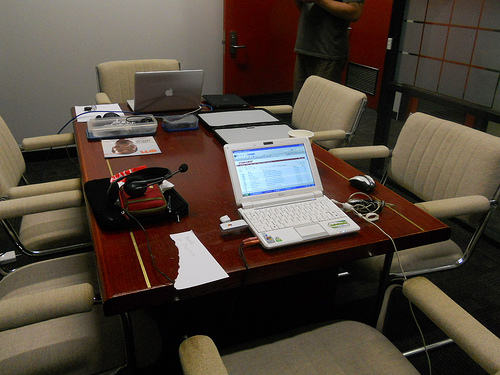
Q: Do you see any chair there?
A: Yes, there is a chair.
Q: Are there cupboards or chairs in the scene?
A: Yes, there is a chair.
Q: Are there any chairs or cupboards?
A: Yes, there is a chair.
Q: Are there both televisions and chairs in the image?
A: No, there is a chair but no televisions.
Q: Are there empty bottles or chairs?
A: Yes, there is an empty chair.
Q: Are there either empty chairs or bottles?
A: Yes, there is an empty chair.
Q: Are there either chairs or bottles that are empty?
A: Yes, the chair is empty.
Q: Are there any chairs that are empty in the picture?
A: Yes, there is an empty chair.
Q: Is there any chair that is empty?
A: Yes, there is a chair that is empty.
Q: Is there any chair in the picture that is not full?
A: Yes, there is a empty chair.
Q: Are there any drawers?
A: No, there are no drawers.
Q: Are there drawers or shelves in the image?
A: No, there are no drawers or shelves.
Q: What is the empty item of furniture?
A: The piece of furniture is a chair.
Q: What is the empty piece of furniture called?
A: The piece of furniture is a chair.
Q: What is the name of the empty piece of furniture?
A: The piece of furniture is a chair.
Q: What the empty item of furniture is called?
A: The piece of furniture is a chair.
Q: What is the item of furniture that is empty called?
A: The piece of furniture is a chair.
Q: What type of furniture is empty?
A: The furniture is a chair.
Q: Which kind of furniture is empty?
A: The furniture is a chair.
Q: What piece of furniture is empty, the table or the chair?
A: The chair is empty.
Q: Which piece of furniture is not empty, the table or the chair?
A: The table is not empty.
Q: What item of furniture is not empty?
A: The piece of furniture is a table.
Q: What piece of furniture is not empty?
A: The piece of furniture is a table.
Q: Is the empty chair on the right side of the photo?
A: Yes, the chair is on the right of the image.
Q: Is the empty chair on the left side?
A: No, the chair is on the right of the image.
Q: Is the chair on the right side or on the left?
A: The chair is on the right of the image.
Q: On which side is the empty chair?
A: The chair is on the right of the image.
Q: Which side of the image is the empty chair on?
A: The chair is on the right of the image.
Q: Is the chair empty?
A: Yes, the chair is empty.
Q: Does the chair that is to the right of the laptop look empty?
A: Yes, the chair is empty.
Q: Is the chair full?
A: No, the chair is empty.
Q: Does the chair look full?
A: No, the chair is empty.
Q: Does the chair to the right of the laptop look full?
A: No, the chair is empty.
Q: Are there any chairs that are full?
A: No, there is a chair but it is empty.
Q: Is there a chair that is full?
A: No, there is a chair but it is empty.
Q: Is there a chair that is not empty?
A: No, there is a chair but it is empty.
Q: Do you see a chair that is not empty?
A: No, there is a chair but it is empty.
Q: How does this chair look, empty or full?
A: The chair is empty.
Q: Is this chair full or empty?
A: The chair is empty.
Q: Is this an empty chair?
A: Yes, this is an empty chair.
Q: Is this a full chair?
A: No, this is an empty chair.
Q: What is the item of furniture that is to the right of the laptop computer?
A: The piece of furniture is a chair.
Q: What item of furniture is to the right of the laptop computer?
A: The piece of furniture is a chair.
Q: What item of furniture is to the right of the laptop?
A: The piece of furniture is a chair.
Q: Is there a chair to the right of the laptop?
A: Yes, there is a chair to the right of the laptop.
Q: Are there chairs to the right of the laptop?
A: Yes, there is a chair to the right of the laptop.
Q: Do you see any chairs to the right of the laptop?
A: Yes, there is a chair to the right of the laptop.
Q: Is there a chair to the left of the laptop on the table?
A: No, the chair is to the right of the laptop computer.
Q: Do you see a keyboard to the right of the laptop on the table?
A: No, there is a chair to the right of the laptop.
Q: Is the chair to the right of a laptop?
A: Yes, the chair is to the right of a laptop.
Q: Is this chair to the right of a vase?
A: No, the chair is to the right of a laptop.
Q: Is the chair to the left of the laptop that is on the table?
A: No, the chair is to the right of the laptop.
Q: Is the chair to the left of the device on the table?
A: No, the chair is to the right of the laptop.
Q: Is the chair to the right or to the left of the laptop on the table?
A: The chair is to the right of the laptop.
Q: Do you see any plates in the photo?
A: No, there are no plates.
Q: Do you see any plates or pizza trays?
A: No, there are no plates or pizza trays.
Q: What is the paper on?
A: The paper is on the table.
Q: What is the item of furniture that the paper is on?
A: The piece of furniture is a table.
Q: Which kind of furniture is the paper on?
A: The paper is on the table.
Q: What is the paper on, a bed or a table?
A: The paper is on a table.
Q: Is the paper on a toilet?
A: No, the paper is on the table.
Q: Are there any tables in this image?
A: Yes, there is a table.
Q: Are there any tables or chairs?
A: Yes, there is a table.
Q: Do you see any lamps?
A: No, there are no lamps.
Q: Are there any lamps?
A: No, there are no lamps.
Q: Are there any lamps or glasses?
A: No, there are no lamps or glasses.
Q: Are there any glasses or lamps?
A: No, there are no lamps or glasses.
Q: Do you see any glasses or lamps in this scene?
A: No, there are no lamps or glasses.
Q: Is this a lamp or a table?
A: This is a table.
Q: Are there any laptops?
A: Yes, there is a laptop.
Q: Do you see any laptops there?
A: Yes, there is a laptop.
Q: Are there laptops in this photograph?
A: Yes, there is a laptop.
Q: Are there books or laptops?
A: Yes, there is a laptop.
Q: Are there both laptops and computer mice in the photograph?
A: Yes, there are both a laptop and a computer mouse.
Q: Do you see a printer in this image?
A: No, there are no printers.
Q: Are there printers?
A: No, there are no printers.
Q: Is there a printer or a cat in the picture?
A: No, there are no printers or cats.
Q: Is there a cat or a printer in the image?
A: No, there are no printers or cats.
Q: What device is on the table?
A: The device is a laptop.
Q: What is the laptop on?
A: The laptop is on the table.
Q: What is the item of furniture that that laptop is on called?
A: The piece of furniture is a table.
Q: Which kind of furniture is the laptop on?
A: The laptop is on the table.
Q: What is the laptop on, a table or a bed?
A: The laptop is on a table.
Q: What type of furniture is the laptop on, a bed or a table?
A: The laptop is on a table.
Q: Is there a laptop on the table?
A: Yes, there is a laptop on the table.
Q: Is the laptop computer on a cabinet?
A: No, the laptop computer is on the table.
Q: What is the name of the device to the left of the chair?
A: The device is a laptop.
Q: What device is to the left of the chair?
A: The device is a laptop.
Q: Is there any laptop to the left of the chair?
A: Yes, there is a laptop to the left of the chair.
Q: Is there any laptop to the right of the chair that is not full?
A: No, the laptop is to the left of the chair.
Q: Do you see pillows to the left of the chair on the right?
A: No, there is a laptop to the left of the chair.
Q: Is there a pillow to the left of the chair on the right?
A: No, there is a laptop to the left of the chair.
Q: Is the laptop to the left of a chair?
A: Yes, the laptop is to the left of a chair.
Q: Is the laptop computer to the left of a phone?
A: No, the laptop computer is to the left of a chair.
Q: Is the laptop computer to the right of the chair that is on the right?
A: No, the laptop computer is to the left of the chair.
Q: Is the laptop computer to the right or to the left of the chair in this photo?
A: The laptop computer is to the left of the chair.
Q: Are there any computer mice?
A: Yes, there is a computer mouse.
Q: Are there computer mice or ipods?
A: Yes, there is a computer mouse.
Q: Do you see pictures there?
A: No, there are no pictures.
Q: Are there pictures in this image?
A: No, there are no pictures.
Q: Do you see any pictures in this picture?
A: No, there are no pictures.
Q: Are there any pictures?
A: No, there are no pictures.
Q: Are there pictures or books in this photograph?
A: No, there are no pictures or books.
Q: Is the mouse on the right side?
A: Yes, the mouse is on the right of the image.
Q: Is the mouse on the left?
A: No, the mouse is on the right of the image.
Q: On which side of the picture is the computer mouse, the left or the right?
A: The computer mouse is on the right of the image.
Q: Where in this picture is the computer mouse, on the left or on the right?
A: The computer mouse is on the right of the image.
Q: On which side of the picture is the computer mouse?
A: The computer mouse is on the right of the image.